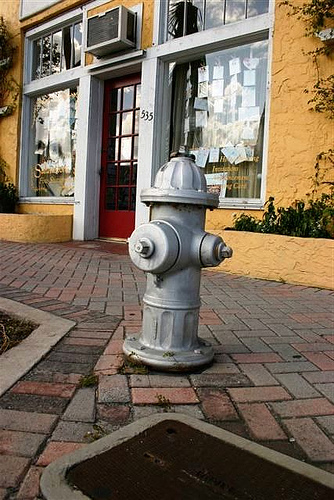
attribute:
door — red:
[102, 73, 142, 238]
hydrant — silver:
[120, 146, 234, 374]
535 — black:
[139, 106, 156, 125]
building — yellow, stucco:
[273, 6, 304, 201]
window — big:
[26, 95, 77, 200]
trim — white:
[74, 70, 98, 244]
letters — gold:
[212, 154, 260, 189]